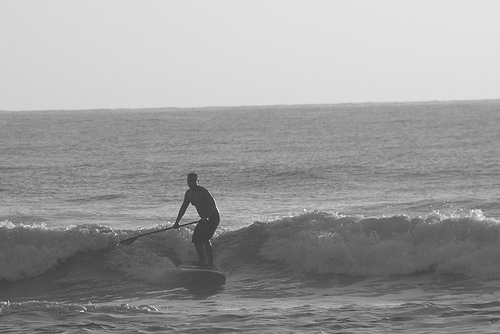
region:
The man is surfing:
[105, 154, 333, 296]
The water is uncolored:
[21, 108, 480, 302]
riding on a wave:
[20, 182, 482, 330]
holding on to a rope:
[117, 208, 202, 260]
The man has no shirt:
[182, 184, 226, 242]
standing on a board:
[179, 238, 222, 288]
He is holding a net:
[107, 212, 217, 258]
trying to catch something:
[112, 164, 222, 293]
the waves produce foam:
[1, 204, 486, 322]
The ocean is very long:
[31, 87, 483, 222]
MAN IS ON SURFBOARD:
[93, 164, 263, 312]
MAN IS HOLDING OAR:
[109, 214, 217, 264]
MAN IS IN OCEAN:
[15, 90, 493, 326]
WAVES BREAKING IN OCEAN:
[246, 195, 498, 292]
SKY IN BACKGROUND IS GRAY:
[6, 0, 489, 107]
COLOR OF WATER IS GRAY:
[7, 105, 488, 167]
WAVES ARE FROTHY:
[255, 206, 494, 313]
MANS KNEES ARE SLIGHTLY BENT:
[168, 203, 252, 278]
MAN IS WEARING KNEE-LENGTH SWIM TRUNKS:
[164, 206, 246, 253]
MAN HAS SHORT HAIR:
[159, 147, 232, 217]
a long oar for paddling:
[111, 222, 195, 249]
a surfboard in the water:
[175, 260, 225, 277]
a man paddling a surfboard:
[121, 174, 231, 284]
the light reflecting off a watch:
[201, 215, 211, 225]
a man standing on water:
[163, 171, 231, 286]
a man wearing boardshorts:
[173, 173, 223, 268]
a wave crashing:
[250, 198, 489, 287]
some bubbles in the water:
[322, 272, 430, 307]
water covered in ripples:
[292, 119, 462, 187]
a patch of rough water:
[8, 290, 158, 320]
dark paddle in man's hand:
[113, 229, 199, 249]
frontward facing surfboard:
[151, 255, 246, 309]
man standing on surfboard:
[171, 170, 226, 265]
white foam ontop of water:
[328, 212, 488, 295]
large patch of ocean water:
[318, 96, 463, 198]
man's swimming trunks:
[184, 215, 249, 253]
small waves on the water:
[42, 289, 162, 326]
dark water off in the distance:
[21, 103, 95, 175]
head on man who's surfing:
[186, 164, 203, 193]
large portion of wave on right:
[286, 194, 498, 289]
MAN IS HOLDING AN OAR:
[117, 213, 219, 248]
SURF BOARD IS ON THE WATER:
[151, 246, 237, 293]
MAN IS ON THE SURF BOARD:
[165, 160, 230, 306]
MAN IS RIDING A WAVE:
[5, 146, 490, 286]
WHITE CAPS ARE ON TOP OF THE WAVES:
[255, 206, 455, 266]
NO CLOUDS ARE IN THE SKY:
[7, 6, 462, 86]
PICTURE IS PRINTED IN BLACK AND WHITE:
[7, 14, 497, 322]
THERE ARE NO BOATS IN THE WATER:
[21, 118, 485, 189]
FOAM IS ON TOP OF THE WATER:
[6, 293, 161, 324]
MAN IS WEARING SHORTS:
[191, 203, 221, 253]